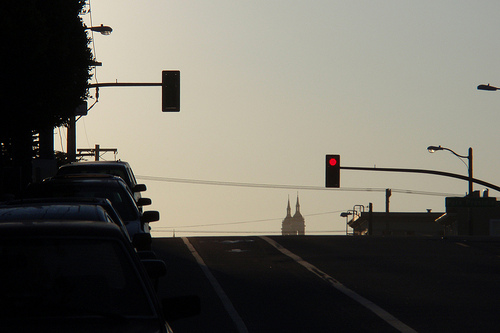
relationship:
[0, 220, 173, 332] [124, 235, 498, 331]
car on street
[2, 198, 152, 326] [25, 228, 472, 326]
car is on street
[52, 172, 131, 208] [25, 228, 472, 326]
car is on street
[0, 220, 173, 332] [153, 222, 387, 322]
car on street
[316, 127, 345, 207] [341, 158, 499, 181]
light on pole